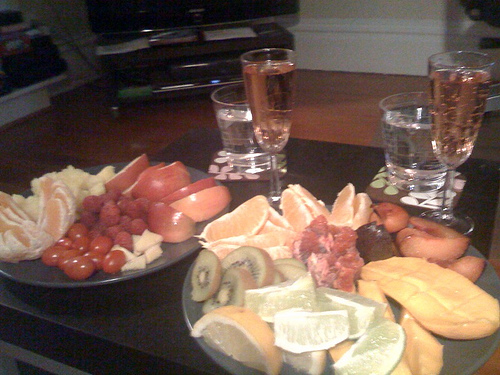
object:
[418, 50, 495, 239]
champagne glass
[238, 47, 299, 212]
champagne glass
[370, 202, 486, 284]
peach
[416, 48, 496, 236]
glass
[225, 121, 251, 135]
water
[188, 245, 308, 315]
kiwi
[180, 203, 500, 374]
fruit plates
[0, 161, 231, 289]
fruit plates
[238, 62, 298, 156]
champagne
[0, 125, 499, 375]
table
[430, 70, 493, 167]
wine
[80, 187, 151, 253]
raspberries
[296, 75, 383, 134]
floor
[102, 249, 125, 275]
grape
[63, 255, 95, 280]
grape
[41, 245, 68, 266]
grape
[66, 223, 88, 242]
grape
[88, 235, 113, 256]
grape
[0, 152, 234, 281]
fruit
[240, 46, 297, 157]
clear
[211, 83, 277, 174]
glass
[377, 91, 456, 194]
glass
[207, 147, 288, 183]
coaster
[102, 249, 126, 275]
tomatoe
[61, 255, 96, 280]
tomatoe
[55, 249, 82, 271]
tomatoe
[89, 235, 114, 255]
tomatoe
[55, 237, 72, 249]
tomatoe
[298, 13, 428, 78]
baseboard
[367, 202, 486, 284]
tomatoes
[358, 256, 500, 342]
bread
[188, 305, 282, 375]
orange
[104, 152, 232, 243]
apple slices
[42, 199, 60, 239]
orange section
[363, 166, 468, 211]
napkin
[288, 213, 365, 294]
raspberries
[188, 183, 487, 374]
fruit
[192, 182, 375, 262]
orange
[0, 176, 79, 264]
orange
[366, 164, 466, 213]
coaster